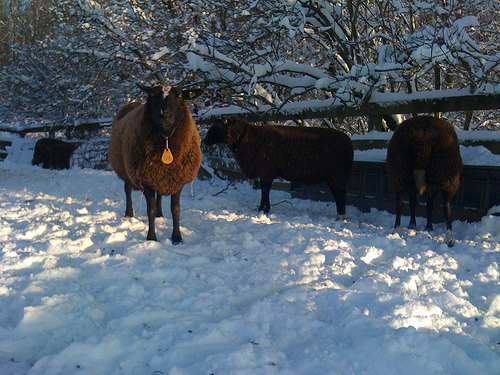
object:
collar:
[161, 126, 177, 164]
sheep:
[202, 114, 354, 222]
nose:
[160, 111, 172, 120]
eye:
[148, 92, 155, 97]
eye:
[179, 92, 183, 97]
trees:
[0, 0, 493, 139]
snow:
[1, 179, 486, 351]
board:
[108, 82, 204, 249]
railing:
[192, 85, 499, 124]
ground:
[319, 87, 350, 107]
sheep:
[385, 114, 462, 245]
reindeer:
[0, 173, 500, 375]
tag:
[161, 147, 174, 164]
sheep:
[107, 82, 204, 244]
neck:
[145, 104, 187, 135]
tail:
[410, 145, 430, 197]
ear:
[135, 82, 151, 93]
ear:
[183, 88, 205, 100]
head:
[135, 83, 204, 131]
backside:
[386, 115, 462, 231]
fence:
[0, 84, 498, 154]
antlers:
[136, 82, 154, 94]